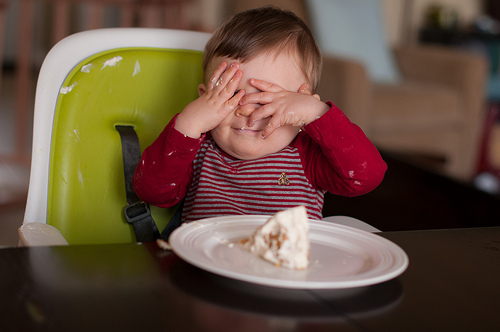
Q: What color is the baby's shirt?
A: Red.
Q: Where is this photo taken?
A: At a table.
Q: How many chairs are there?
A: One.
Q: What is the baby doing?
A: Covering his eyes.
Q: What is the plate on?
A: A table.